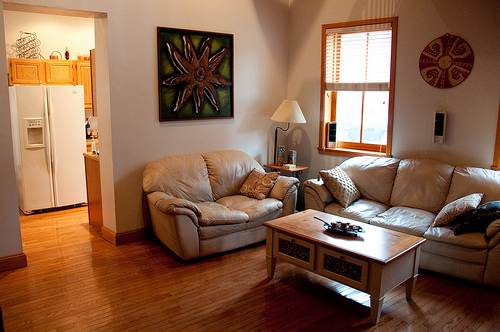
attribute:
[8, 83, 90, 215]
refrigerator — white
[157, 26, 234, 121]
painting — in the picture, red, large, brown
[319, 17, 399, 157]
window frame — wooden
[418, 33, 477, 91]
decoration — orange, round, tan, painting, circular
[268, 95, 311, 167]
lamp — white, stand alone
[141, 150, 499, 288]
couch — beige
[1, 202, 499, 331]
floor — wooden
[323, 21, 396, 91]
mini blinds — open, white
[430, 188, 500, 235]
two pillows — square, decorative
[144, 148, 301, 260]
love seat — cream, leather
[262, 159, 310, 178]
end table — square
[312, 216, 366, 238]
tray — leaf shaped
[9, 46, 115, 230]
cabinets — wooden, light brown, brown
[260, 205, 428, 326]
center table — wooden, brown